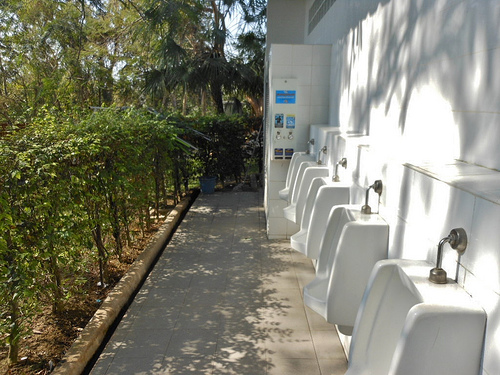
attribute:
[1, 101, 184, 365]
trees — lined up, leafy, short, here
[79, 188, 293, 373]
shadow — black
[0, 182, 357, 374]
ground — cement, dirty, brown, tile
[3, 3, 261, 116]
trees — tall, leafy, palm, brown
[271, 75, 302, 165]
sign — white, condom dispenser, blue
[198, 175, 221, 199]
pot — blue, here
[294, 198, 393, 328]
urinal — white, here, one of many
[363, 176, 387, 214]
pipe — silver, for water, metal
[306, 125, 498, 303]
tile — white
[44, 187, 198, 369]
curb — here